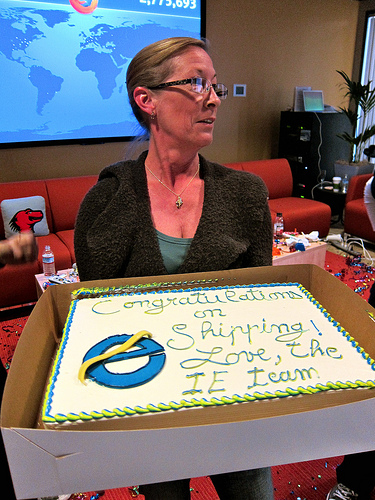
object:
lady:
[71, 30, 274, 285]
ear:
[129, 85, 156, 118]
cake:
[37, 279, 374, 431]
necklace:
[127, 135, 214, 220]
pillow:
[1, 188, 62, 244]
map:
[0, 0, 206, 151]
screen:
[0, 0, 204, 135]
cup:
[329, 173, 343, 194]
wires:
[313, 108, 326, 180]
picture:
[0, 0, 201, 141]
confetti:
[313, 486, 321, 494]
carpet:
[0, 299, 363, 485]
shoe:
[312, 466, 363, 497]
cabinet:
[278, 96, 354, 222]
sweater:
[84, 204, 265, 250]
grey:
[220, 194, 258, 268]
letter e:
[74, 324, 170, 392]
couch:
[2, 152, 336, 315]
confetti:
[295, 480, 305, 490]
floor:
[86, 452, 368, 497]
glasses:
[124, 73, 234, 101]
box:
[4, 259, 373, 500]